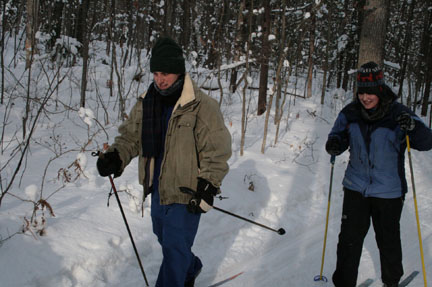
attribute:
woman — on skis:
[313, 56, 432, 286]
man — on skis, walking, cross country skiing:
[95, 34, 234, 286]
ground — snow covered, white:
[2, 27, 432, 286]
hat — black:
[146, 36, 187, 77]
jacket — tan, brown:
[103, 75, 233, 208]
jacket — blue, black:
[321, 86, 431, 203]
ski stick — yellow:
[312, 153, 338, 287]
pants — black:
[326, 190, 411, 287]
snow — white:
[78, 105, 97, 127]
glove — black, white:
[183, 176, 222, 219]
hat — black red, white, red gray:
[354, 60, 399, 106]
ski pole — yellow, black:
[405, 124, 431, 286]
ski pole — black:
[96, 147, 154, 286]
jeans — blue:
[147, 192, 204, 286]